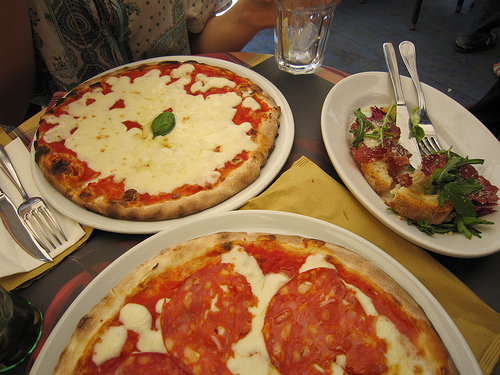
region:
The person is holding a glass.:
[21, 0, 337, 80]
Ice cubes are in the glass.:
[255, 0, 345, 80]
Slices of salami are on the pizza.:
[150, 260, 375, 367]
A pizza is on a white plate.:
[25, 185, 480, 370]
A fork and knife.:
[0, 110, 80, 257]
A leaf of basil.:
[130, 95, 185, 140]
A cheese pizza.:
[30, 45, 300, 222]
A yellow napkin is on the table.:
[231, 150, 491, 365]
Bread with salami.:
[345, 95, 497, 225]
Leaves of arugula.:
[435, 157, 487, 248]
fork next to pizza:
[10, 195, 93, 260]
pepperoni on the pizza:
[118, 243, 475, 373]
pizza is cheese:
[54, 73, 245, 182]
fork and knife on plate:
[381, 95, 469, 203]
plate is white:
[329, 68, 371, 188]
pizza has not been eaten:
[67, 78, 309, 246]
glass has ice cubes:
[269, 10, 338, 119]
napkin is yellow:
[265, 155, 373, 256]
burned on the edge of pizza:
[30, 87, 76, 175]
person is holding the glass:
[235, 1, 333, 43]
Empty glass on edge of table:
[266, 5, 345, 80]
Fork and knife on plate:
[376, 25, 446, 171]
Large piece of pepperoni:
[261, 242, 391, 369]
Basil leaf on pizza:
[126, 102, 193, 147]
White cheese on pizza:
[234, 246, 279, 289]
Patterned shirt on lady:
[40, 8, 165, 56]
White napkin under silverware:
[11, 244, 30, 268]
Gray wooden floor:
[347, 23, 382, 44]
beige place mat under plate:
[301, 162, 328, 203]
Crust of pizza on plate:
[389, 186, 448, 215]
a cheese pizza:
[17, 53, 277, 210]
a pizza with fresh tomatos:
[42, 191, 404, 371]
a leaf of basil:
[136, 98, 203, 151]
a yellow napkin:
[251, 151, 499, 347]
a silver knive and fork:
[0, 108, 100, 256]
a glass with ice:
[274, 1, 347, 81]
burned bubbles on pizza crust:
[35, 160, 71, 182]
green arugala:
[422, 166, 497, 240]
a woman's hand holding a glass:
[183, 0, 333, 68]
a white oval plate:
[299, 54, 499, 299]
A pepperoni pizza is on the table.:
[33, 220, 465, 371]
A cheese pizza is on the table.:
[20, 40, 306, 236]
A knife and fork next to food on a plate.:
[325, 25, 496, 260]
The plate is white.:
[311, 41, 497, 241]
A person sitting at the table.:
[27, 0, 288, 65]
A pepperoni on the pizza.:
[151, 261, 258, 369]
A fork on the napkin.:
[2, 150, 83, 250]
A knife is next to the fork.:
[3, 192, 49, 273]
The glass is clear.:
[267, 5, 340, 76]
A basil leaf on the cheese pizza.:
[141, 103, 188, 145]